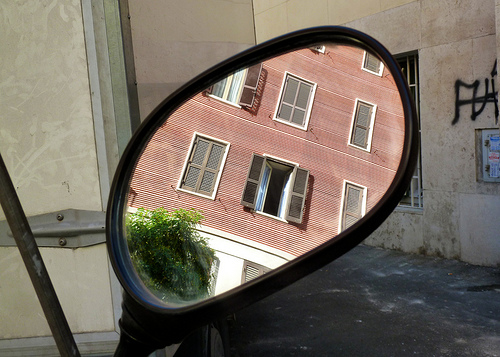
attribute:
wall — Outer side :
[257, 6, 491, 256]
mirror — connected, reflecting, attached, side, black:
[115, 23, 417, 304]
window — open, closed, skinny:
[256, 155, 298, 221]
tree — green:
[130, 208, 214, 303]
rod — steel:
[0, 155, 82, 355]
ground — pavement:
[226, 240, 499, 356]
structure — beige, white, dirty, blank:
[128, 2, 499, 268]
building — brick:
[123, 43, 405, 294]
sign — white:
[480, 127, 499, 184]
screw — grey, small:
[56, 213, 66, 220]